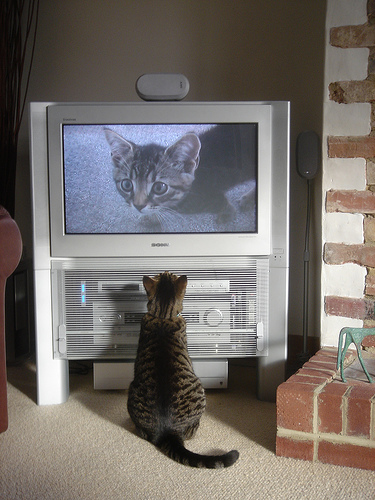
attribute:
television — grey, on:
[45, 109, 277, 248]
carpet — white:
[256, 463, 272, 471]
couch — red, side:
[65, 266, 320, 457]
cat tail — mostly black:
[154, 431, 241, 473]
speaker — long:
[134, 72, 189, 99]